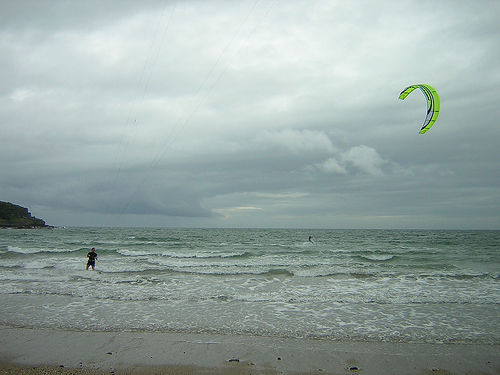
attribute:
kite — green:
[385, 75, 454, 134]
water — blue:
[40, 226, 224, 286]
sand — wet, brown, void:
[42, 328, 159, 370]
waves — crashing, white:
[266, 261, 326, 294]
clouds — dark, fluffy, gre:
[98, 41, 200, 116]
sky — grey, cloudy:
[4, 9, 460, 76]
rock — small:
[218, 347, 238, 374]